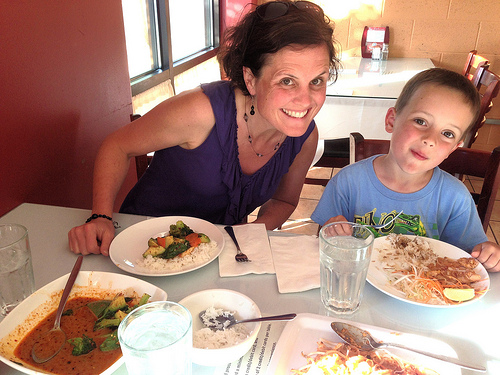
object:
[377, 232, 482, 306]
food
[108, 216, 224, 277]
plate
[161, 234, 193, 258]
vegetables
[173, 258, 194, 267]
rice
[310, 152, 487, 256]
tshirt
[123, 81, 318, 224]
blouse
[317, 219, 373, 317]
glass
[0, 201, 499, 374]
table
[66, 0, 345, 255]
woman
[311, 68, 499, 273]
boy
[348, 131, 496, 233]
chair